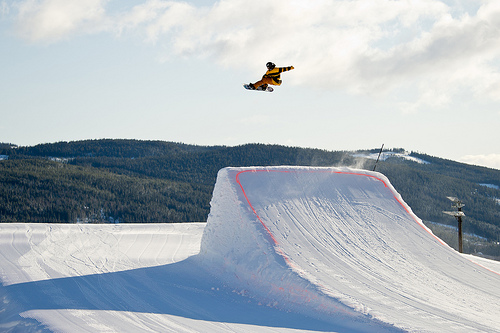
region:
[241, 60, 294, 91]
a snow boarder in air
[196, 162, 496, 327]
a tall snow ramp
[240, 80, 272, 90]
a large snow board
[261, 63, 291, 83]
a yellow and black jacket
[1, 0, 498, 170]
a cloudy grey sky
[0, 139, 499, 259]
a tree covered hillside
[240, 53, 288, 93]
person doing trick in air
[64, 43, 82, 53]
white clouds in blue sky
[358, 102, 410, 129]
white clouds in blue sky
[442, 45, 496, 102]
white clouds in blue sky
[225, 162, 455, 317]
snow ramp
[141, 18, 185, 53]
white clouds in blue sky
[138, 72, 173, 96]
white clouds in blue sky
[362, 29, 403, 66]
white clouds in blue sky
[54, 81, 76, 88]
white clouds in blue sky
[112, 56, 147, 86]
white clouds in blue sky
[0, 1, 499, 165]
clouds in daytime sky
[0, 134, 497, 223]
hills covered with trees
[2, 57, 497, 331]
airborne snowboarder above snowy ramp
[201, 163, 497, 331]
lines on surface of snow covered ramp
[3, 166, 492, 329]
shadow on left side of ramp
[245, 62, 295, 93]
snowboarder in yellow and black jacket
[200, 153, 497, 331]
snow dust above ramp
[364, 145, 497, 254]
patches of snow among trees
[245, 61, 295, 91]
snowboarder with extended arm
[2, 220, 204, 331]
light reflection on snow surface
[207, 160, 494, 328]
a ramp made of snow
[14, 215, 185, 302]
the ground covered in snow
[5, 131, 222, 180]
a hillside covered with trees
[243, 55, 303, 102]
a person in the air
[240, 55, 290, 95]
a person with a snow board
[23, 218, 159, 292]
tracks in the snow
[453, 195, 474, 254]
a wood electrical pole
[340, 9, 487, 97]
white clouds in the sky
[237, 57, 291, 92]
person doing trick in air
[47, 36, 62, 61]
white clouds in blue sky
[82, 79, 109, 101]
white clouds in blue sky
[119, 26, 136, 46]
white clouds in blue sky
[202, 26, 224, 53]
white clouds in blue sky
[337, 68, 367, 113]
white clouds in blue sky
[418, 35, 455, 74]
white clouds in blue sky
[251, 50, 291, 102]
THIS IS A PERSON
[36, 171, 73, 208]
THESE ARE TREES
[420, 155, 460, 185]
THESE ARE GREEN TREES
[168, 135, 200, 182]
THESE ARE GREEN TREES